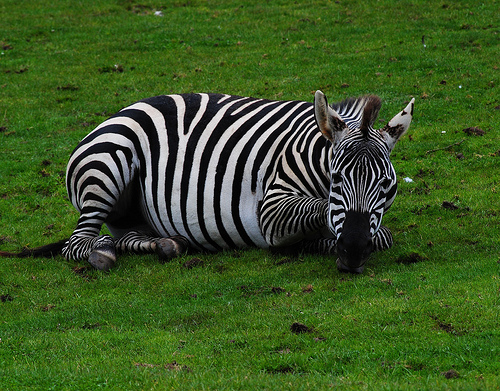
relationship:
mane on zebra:
[348, 87, 404, 128] [111, 88, 408, 233]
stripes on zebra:
[120, 118, 285, 202] [111, 88, 408, 233]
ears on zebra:
[305, 98, 440, 138] [111, 88, 408, 233]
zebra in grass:
[111, 88, 408, 233] [188, 20, 347, 72]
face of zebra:
[336, 141, 392, 278] [111, 88, 408, 233]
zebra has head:
[111, 88, 408, 233] [300, 99, 481, 341]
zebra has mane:
[111, 88, 408, 233] [348, 87, 404, 128]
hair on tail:
[13, 230, 68, 268] [1, 229, 110, 347]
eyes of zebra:
[320, 147, 401, 202] [111, 88, 408, 233]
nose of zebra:
[349, 207, 398, 255] [111, 88, 408, 233]